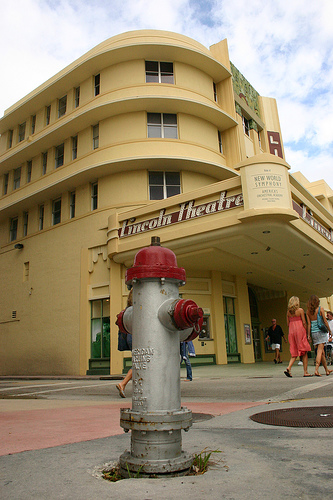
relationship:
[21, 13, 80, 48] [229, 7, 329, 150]
clouds in sky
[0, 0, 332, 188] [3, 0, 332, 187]
clouds in sky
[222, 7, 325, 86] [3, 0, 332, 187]
clouds in sky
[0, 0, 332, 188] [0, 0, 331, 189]
clouds in blue sky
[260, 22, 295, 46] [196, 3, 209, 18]
clouds in sky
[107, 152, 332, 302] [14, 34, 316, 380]
front awning on theater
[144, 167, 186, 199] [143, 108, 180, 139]
window above window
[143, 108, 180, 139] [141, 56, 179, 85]
window above window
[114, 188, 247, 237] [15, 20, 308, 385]
word on building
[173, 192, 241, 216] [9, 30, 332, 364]
word on building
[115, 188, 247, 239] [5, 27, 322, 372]
words on theatre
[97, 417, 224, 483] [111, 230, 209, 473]
base on hydrant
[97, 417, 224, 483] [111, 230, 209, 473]
base below hydrant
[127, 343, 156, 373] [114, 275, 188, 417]
word on hydrant